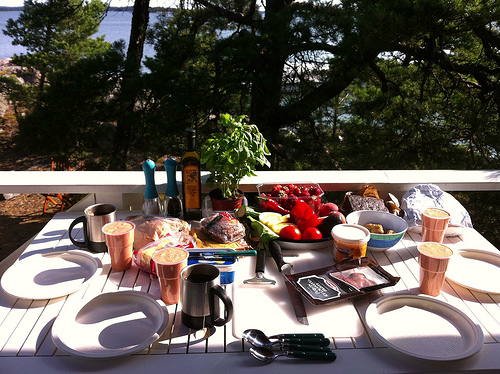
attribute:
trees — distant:
[109, 0, 149, 169]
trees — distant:
[195, 0, 497, 170]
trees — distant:
[1, 0, 130, 157]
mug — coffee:
[178, 261, 233, 329]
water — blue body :
[1, 6, 496, 158]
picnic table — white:
[137, 189, 294, 338]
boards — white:
[1, 314, 48, 352]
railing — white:
[22, 151, 497, 204]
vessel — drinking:
[420, 203, 447, 249]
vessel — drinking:
[419, 241, 449, 293]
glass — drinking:
[106, 220, 133, 269]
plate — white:
[51, 289, 168, 359]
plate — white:
[364, 294, 481, 364]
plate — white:
[1, 250, 101, 300]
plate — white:
[440, 246, 499, 291]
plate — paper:
[360, 285, 490, 367]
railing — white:
[5, 157, 497, 197]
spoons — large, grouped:
[232, 281, 361, 371]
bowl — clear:
[258, 182, 325, 212]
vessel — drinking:
[174, 260, 236, 341]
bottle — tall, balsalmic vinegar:
[174, 122, 204, 223]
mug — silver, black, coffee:
[168, 261, 248, 337]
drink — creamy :
[153, 247, 186, 272]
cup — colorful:
[153, 246, 187, 301]